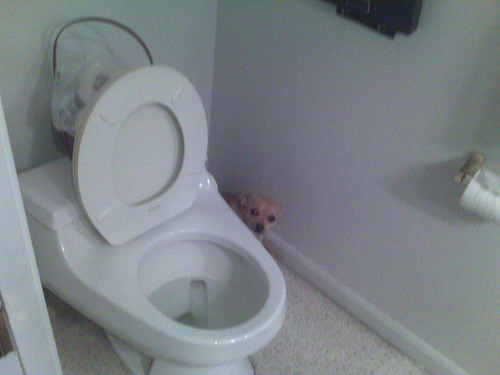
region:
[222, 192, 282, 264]
Small dog hiding in bathroom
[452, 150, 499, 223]
Toilet paper on toilet paper holder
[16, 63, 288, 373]
Toilet in bathroom with seat up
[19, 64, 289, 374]
Small dog hiding next to toilet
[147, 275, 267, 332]
Water inside of toilet bowl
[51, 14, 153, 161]
Wicker basket on back of toilet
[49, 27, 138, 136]
Extra toilet paper roll inside plastic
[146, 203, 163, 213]
Logo on toilet seat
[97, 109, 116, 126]
Stopper on bottom of toilet seat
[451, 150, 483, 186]
Toilet paper holder attached to wall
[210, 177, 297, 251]
A dog is behind the toilet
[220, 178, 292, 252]
A small dog is looking at the camera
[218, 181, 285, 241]
The dog's coat is light brown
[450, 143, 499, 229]
A roll of toilet paper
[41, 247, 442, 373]
Light tan colored carpet is covering the ground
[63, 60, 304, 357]
The toilet seat is up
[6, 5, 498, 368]
Photo was taken indoors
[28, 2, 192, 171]
A basket is behind the toilet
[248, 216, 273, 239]
Dog's nose is black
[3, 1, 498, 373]
The corner view of the bathroom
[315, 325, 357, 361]
white carpet on floor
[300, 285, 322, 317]
white carpet on floor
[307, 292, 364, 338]
white carpet on floor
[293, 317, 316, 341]
white carpet on floor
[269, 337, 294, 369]
white carpet on floor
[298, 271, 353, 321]
white carpet on floor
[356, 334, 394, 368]
white carpet on floor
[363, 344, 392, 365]
white carpet on floor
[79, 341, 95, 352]
white carpet on floor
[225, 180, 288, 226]
a dog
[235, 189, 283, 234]
the dog is brown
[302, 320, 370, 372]
the floor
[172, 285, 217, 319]
water in the toilet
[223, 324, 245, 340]
the rim of the toilet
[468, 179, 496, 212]
the toilet tissue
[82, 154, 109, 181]
the toilet seat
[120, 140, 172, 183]
the lid of the toilet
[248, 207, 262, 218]
the dogs eye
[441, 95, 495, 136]
a shadow on the wall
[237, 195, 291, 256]
dog in the corner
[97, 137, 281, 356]
white toilet on floor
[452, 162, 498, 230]
toilet paper roll on wall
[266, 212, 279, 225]
eye of the dog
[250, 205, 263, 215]
eye of the dog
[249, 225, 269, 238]
nose of hte dog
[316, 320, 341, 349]
patch of the floor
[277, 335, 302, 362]
patch of the floor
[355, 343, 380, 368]
patch of the floor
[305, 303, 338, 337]
patch of the floor